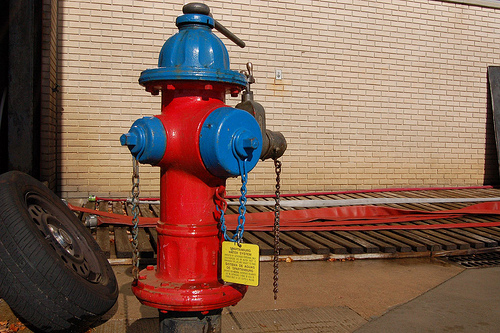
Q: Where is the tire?
A: To the left of the fire hydrant.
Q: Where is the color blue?
A: The top and plugs of the hydrant.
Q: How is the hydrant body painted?
A: Red.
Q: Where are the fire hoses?
A: On the pallet.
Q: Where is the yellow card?
A: Hanging from the hydrant.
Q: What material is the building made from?
A: Bricks.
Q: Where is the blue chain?
A: On the center plug.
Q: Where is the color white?
A: On the building.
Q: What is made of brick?
A: Wall.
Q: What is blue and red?
A: Hydrant.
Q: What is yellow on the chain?
A: Tag.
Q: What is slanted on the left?
A: Tire.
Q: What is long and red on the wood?
A: Hose.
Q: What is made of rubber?
A: Tire.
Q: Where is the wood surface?
A: On ground.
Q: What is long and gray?
A: Hose.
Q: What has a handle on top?
A: Hydrant.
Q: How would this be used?
A: To put out fires.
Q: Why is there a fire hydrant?
A: To put out a fire.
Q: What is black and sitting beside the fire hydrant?
A: Tire.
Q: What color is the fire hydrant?
A: Blue and red.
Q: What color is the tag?
A: Yellow.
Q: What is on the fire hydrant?
A: A tag.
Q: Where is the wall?
A: Behind the fire hydrant.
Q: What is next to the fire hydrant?
A: A wheel.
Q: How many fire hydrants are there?
A: One.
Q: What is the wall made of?
A: Brick.